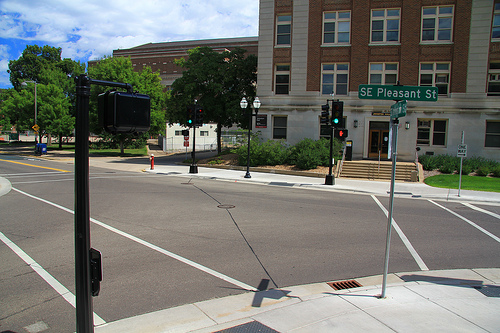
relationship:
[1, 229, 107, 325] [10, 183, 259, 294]
line parallel to line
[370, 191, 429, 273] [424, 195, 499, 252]
line parallel to line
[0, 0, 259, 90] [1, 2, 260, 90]
clouds up in sky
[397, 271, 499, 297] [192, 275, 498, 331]
shadow cast on sidewalk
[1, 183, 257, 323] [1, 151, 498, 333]
crosswalk across road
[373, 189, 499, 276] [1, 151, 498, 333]
crosswalk across road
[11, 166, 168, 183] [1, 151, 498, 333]
crosswalk across road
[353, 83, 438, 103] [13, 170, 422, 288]
street sign at intersection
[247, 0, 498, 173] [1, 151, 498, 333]
building along road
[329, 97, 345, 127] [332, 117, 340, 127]
light fixture with traffic light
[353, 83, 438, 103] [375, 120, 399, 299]
street sign on top of pole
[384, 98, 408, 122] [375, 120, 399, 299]
street sign on top of pole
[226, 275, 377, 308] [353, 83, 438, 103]
shadow of street sign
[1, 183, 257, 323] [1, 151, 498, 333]
crosswalk painted on road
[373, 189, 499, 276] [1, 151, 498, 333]
crosswalk painted on road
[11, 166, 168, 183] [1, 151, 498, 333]
crosswalk painted on road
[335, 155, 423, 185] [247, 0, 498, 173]
steps in front of building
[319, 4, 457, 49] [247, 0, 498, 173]
windows on side of building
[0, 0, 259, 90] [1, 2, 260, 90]
clouds in sky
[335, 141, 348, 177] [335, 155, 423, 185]
railing over steps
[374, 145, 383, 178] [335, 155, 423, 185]
railing over steps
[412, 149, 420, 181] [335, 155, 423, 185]
railing over steps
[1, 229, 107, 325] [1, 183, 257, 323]
line on crosswalk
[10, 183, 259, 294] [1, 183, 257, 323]
line on crosswalk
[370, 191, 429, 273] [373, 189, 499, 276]
line on crosswalk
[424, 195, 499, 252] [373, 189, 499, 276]
line on crosswalk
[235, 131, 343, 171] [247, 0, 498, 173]
bushes in front of building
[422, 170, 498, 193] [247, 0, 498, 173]
grass in front of building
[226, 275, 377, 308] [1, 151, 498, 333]
shadow cast on road